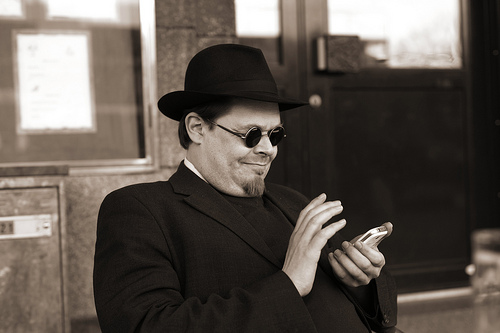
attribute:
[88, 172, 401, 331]
suit jacket — black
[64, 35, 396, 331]
man — light skinned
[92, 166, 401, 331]
suit — black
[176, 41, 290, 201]
head — down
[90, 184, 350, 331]
arm — bent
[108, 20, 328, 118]
hat — black